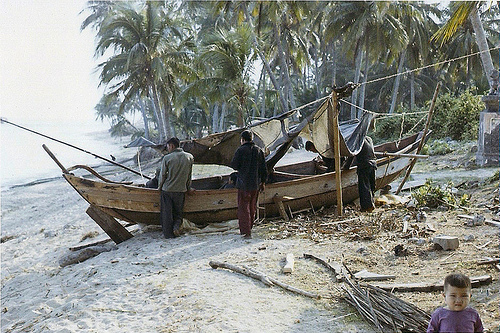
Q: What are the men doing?
A: Working on the boat.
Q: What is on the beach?
A: Wooden boat.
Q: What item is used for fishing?
A: A boat.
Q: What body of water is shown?
A: The ocean.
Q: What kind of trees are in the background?
A: Palm trees.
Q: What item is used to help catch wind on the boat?
A: The sail.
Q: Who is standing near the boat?
A: Three men.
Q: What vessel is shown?
A: A boat.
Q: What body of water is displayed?
A: The ocean.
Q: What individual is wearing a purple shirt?
A: A young child.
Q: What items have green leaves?
A: Palm trees.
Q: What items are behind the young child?
A: Wooden sticks.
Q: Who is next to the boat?
A: Three people next to a boat.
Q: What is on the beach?
A: A wooden boat on the beach.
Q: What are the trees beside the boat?
A: These are palm trees beside the boat.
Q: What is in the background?
A: A forest of palm trees.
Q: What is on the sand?
A: An old wooden boat.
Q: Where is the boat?
A: Sitting on a beach.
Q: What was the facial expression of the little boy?
A: Hungry and confused.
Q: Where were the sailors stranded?
A: Near yellow river.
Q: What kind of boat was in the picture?
A: A canoe.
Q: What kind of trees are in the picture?
A: Palm trees.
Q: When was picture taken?
A: Daytime.